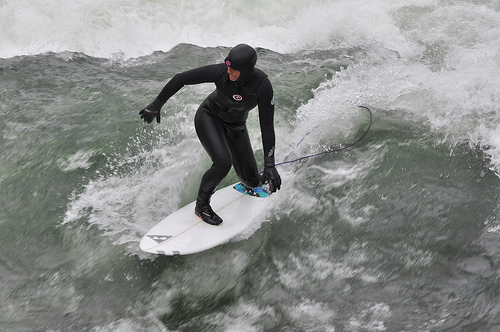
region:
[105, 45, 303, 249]
a person riding on a surfboard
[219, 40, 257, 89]
the head of a person surfing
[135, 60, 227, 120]
the arm of a person surfing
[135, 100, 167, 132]
the hand of a person surfing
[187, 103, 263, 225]
the legs of a person surfing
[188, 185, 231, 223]
the foot of a person surfing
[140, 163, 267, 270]
a large white board for surfing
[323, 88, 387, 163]
the rope of a surfboard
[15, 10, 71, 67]
a wave that is crashing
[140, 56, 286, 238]
a person surfing in the ocean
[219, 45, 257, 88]
the head of a person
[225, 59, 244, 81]
the face of a person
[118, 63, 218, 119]
the right arm of a person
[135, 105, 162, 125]
the right arm of a person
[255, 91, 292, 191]
the left arm of a person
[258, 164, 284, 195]
the left hand of a person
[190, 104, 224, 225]
the right leg of a person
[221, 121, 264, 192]
the left leg of a person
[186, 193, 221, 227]
the right leg of a person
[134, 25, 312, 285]
surfer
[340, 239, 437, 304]
white and gray ocean waves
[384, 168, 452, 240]
white and gray ocean waves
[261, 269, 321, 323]
white and gray ocean waves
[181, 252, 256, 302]
white and gray ocean waves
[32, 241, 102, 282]
white and gray ocean waves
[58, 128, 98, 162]
white and gray ocean waves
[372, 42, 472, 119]
white and gray ocean waves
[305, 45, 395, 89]
white and gray ocean waves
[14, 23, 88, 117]
white and gray ocean waves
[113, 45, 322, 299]
the woman on surfboard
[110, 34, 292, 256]
the woman on surfboard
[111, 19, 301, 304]
the woman on surfboard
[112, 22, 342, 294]
the woman on surfboard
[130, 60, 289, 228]
the suit is black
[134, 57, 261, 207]
the suit is black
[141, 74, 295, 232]
the suit is black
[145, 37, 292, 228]
the suit is black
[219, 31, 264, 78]
head of a person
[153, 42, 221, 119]
arm of a person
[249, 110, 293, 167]
arm of a person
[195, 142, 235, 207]
leg of a person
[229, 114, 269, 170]
thigh of a person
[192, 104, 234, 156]
thigh of a person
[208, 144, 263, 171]
knee of a person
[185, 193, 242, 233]
feet of a person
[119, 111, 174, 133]
hand of a person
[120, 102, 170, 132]
finger of a person